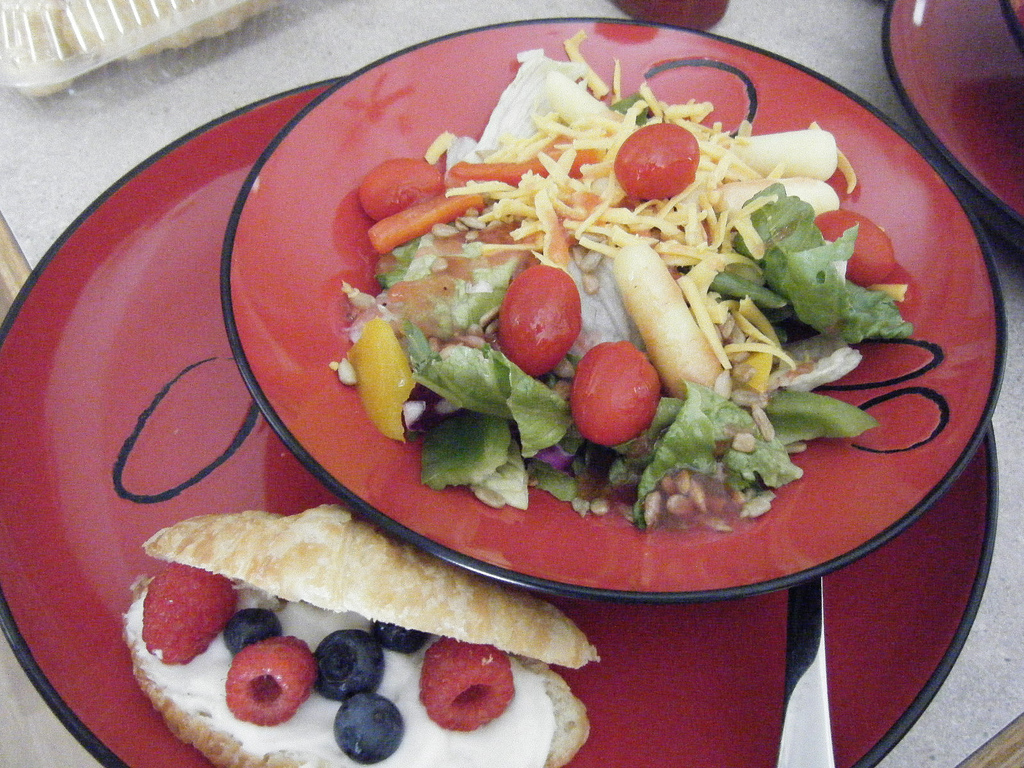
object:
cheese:
[614, 210, 756, 288]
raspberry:
[215, 636, 308, 725]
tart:
[113, 504, 596, 764]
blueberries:
[332, 686, 409, 758]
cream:
[493, 716, 538, 764]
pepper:
[393, 254, 428, 288]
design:
[113, 334, 257, 506]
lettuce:
[373, 328, 581, 468]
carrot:
[373, 181, 490, 244]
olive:
[567, 440, 615, 506]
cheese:
[543, 110, 614, 148]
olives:
[223, 602, 279, 638]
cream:
[403, 675, 420, 759]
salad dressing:
[633, 476, 775, 546]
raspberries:
[424, 638, 523, 732]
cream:
[395, 690, 482, 762]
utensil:
[775, 601, 831, 765]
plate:
[887, 2, 1024, 230]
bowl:
[232, 15, 1007, 607]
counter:
[13, 5, 1020, 746]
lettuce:
[457, 48, 594, 174]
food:
[336, 262, 440, 464]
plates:
[13, 33, 1002, 763]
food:
[325, 95, 936, 501]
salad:
[439, 144, 815, 454]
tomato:
[610, 116, 695, 208]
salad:
[337, 32, 898, 509]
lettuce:
[399, 396, 527, 490]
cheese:
[521, 147, 608, 208]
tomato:
[812, 198, 897, 286]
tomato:
[497, 248, 582, 372]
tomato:
[353, 160, 433, 216]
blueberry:
[316, 629, 385, 696]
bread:
[141, 503, 601, 672]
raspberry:
[145, 553, 225, 675]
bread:
[119, 567, 592, 765]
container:
[5, 1, 292, 105]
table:
[24, 1, 1021, 755]